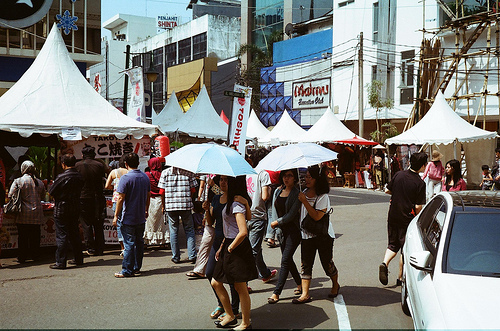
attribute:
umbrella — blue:
[165, 141, 260, 186]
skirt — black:
[209, 237, 266, 291]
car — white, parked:
[395, 182, 498, 331]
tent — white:
[12, 21, 153, 140]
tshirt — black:
[388, 171, 426, 220]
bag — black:
[300, 210, 333, 241]